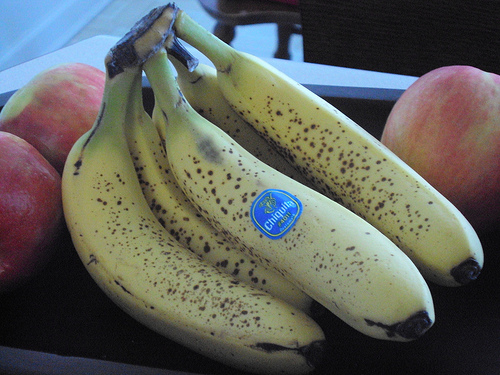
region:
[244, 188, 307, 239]
a blue Chiquita banana label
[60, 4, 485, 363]
a bunch of ripe bananas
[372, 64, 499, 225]
a red and green apple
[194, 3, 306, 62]
a brown wooden chair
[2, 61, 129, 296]
a couple of shiny apples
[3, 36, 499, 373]
a wooden fruit bin with fruit in it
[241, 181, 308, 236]
the sticker is blue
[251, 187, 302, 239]
sticker on the banana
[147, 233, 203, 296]
spots on the banana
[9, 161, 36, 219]
a red apple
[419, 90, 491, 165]
the apple is red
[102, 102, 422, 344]
a batch of bananas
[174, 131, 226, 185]
a banana peel that is yellow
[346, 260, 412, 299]
a yellow banana peel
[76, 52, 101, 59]
a counter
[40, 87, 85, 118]
an apple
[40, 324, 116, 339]
black stone color on surface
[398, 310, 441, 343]
black edge of yellow banana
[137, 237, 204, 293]
brown spots on banans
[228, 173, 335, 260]
blue label on the banana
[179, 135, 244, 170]
small bruise on the banana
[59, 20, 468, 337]
bunch of banana in the tray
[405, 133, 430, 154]
yellow hue on the apple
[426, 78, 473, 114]
pink blush on the apple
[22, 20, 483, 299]
orange and banana in tray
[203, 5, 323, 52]
edge of chair at table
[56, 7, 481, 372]
small bundle of bananas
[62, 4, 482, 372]
a cluster of banana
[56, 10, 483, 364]
several bruised bananas together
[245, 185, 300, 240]
a blue sticker on a banana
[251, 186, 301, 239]
sticker on a banana with a logo on it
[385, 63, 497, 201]
a bright red apple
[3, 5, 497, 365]
a small basket of fruit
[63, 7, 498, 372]
bananas next to an apple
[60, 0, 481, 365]
Bananas in a bunch.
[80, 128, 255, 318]
Yellow bananas with brown spots.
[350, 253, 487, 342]
Brown tips on bananas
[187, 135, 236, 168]
Black spot on banana.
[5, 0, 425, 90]
White counter top in background.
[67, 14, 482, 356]
Yellow bananas with many dark spots.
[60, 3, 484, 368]
a bruised bundle of bananas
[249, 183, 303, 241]
small blue sticker on fruit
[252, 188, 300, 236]
the logo for a banana company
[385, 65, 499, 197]
a small apple in a corner